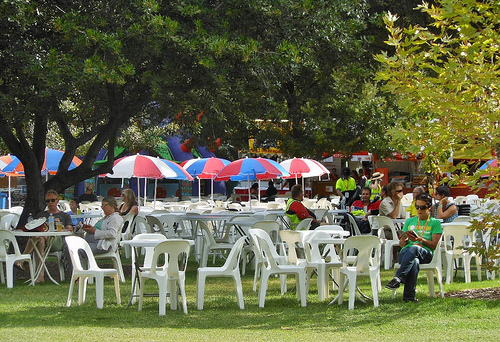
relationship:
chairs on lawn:
[0, 223, 382, 316] [2, 196, 499, 339]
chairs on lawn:
[134, 234, 193, 320] [2, 196, 499, 339]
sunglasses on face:
[414, 202, 431, 210] [415, 201, 426, 218]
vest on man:
[286, 195, 306, 232] [285, 187, 349, 267]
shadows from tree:
[1, 286, 499, 338] [361, 1, 500, 301]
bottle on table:
[47, 213, 58, 232] [8, 227, 75, 290]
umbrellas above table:
[216, 153, 291, 188] [234, 206, 287, 220]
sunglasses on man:
[414, 202, 431, 210] [385, 192, 444, 311]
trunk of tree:
[10, 183, 57, 265] [1, 1, 307, 268]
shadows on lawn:
[1, 286, 499, 338] [2, 196, 499, 339]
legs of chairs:
[64, 273, 124, 308] [0, 223, 382, 316]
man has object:
[385, 192, 444, 311] [396, 227, 417, 242]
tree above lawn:
[361, 1, 500, 301] [2, 196, 499, 339]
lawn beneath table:
[2, 196, 499, 339] [8, 227, 75, 290]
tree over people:
[361, 1, 500, 301] [377, 179, 412, 269]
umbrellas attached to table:
[216, 153, 291, 188] [234, 206, 287, 220]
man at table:
[13, 187, 75, 289] [8, 227, 75, 290]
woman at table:
[60, 190, 126, 281] [8, 227, 75, 290]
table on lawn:
[8, 227, 75, 290] [2, 196, 499, 339]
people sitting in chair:
[13, 188, 139, 284] [22, 247, 62, 285]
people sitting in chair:
[13, 188, 139, 284] [85, 214, 126, 284]